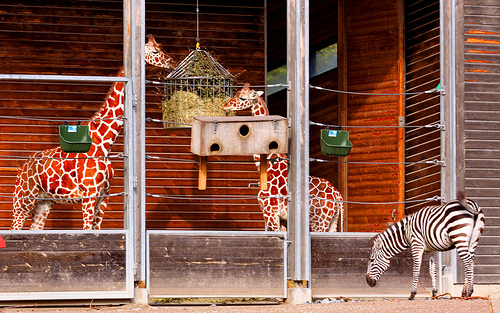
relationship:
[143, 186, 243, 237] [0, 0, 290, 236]
shadow on wall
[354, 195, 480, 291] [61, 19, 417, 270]
zebra outside pen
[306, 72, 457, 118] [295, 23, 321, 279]
cable between post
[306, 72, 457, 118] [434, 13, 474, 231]
cable between post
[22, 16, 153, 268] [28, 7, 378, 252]
giraffe in pen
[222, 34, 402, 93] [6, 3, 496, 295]
windows in enclosure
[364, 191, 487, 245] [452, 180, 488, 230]
zebra swishing tail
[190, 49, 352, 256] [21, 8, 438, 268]
giraffe in cage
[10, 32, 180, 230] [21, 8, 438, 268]
giraffe in cage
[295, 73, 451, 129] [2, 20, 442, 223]
cable on cage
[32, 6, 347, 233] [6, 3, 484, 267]
giraffes inside enclosure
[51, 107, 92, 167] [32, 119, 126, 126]
container hanging from wire